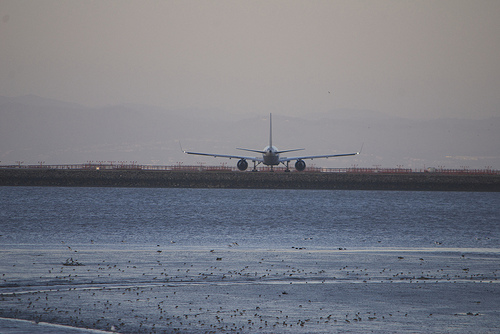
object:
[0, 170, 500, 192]
ground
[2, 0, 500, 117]
grey sky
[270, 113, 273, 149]
tail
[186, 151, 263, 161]
wing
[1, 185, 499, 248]
waves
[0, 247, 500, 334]
shore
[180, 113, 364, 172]
airplane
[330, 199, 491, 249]
water part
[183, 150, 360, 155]
lights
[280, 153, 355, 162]
wing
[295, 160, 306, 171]
engine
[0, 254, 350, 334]
birds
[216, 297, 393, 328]
sand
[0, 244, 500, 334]
beach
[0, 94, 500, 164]
mountains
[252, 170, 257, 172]
wheels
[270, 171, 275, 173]
wheels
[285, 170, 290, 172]
wheels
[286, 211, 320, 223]
part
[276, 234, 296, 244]
part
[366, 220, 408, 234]
part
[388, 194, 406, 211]
part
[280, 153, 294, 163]
part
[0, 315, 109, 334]
edge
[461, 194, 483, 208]
part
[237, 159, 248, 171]
engine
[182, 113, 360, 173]
plane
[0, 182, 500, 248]
water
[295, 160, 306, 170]
propeller